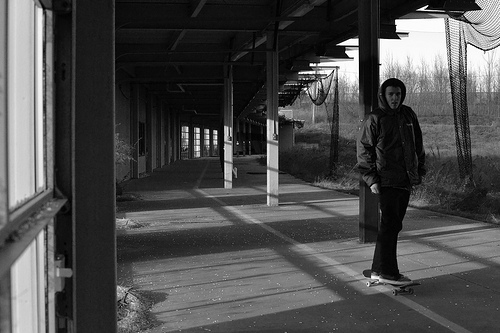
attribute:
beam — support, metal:
[220, 63, 235, 188]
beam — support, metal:
[262, 26, 285, 211]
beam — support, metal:
[354, 11, 382, 244]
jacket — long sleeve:
[355, 77, 426, 192]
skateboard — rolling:
[345, 263, 426, 301]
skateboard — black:
[360, 267, 420, 296]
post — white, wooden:
[268, 39, 275, 115]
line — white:
[195, 181, 476, 319]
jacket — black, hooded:
[357, 106, 438, 196]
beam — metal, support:
[262, 2, 287, 209]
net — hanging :
[436, 9, 498, 217]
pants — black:
[367, 176, 412, 285]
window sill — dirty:
[1, 200, 63, 268]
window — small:
[177, 120, 191, 162]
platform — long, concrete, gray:
[114, 151, 498, 331]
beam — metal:
[347, 8, 392, 243]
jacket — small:
[355, 79, 432, 194]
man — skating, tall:
[356, 77, 426, 278]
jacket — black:
[349, 78, 426, 190]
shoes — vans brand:
[355, 258, 414, 290]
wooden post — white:
[219, 58, 233, 188]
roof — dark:
[119, 0, 477, 132]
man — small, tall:
[352, 73, 428, 284]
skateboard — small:
[357, 265, 424, 298]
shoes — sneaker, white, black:
[349, 237, 426, 288]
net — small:
[429, 13, 499, 178]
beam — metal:
[67, 0, 117, 332]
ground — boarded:
[145, 222, 497, 332]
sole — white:
[374, 280, 417, 290]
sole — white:
[366, 274, 378, 284]